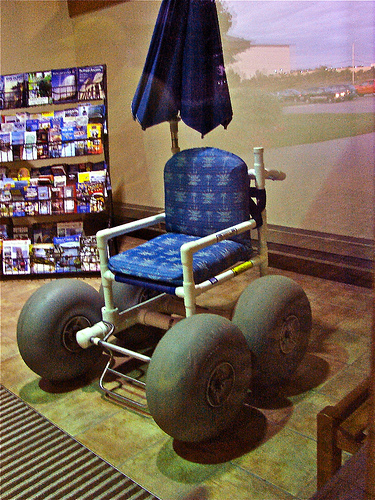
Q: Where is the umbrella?
A: Over chair.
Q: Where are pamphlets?
A: On shelves.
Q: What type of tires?
A: Balloon.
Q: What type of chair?
A: Mobile.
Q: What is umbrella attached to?
A: Chair.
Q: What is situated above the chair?
A: An umbrella.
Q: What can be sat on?
A: A chair.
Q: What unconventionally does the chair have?
A: Wheels.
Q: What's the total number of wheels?
A: 4.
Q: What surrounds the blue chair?
A: Large thick tires.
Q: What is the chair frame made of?
A: Plumbing tubes.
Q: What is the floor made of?
A: Stone brown tiles.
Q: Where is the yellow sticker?
A: On tube under the arm rest.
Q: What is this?
A: A beach chair with tires.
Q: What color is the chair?
A: Blue.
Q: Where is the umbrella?
A: Attached to the chair.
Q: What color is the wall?
A: White.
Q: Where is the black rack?
A: In the back left of the picture.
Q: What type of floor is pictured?
A: Tile.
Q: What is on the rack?
A: Brochures.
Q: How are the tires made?
A: Out of rubber.